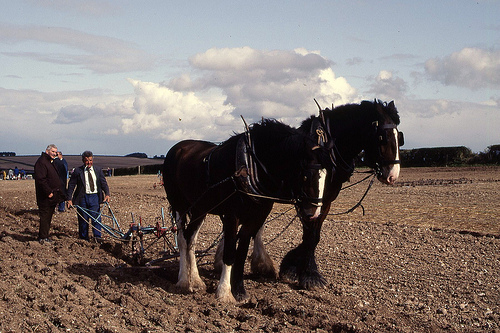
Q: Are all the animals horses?
A: Yes, all the animals are horses.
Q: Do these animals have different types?
A: No, all the animals are horses.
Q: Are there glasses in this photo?
A: No, there are no glasses.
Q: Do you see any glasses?
A: No, there are no glasses.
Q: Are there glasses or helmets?
A: No, there are no glasses or helmets.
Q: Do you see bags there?
A: No, there are no bags.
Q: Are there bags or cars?
A: No, there are no bags or cars.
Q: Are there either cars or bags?
A: No, there are no bags or cars.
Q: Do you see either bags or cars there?
A: No, there are no bags or cars.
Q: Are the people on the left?
A: Yes, the people are on the left of the image.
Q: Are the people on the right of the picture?
A: No, the people are on the left of the image.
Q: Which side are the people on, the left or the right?
A: The people are on the left of the image.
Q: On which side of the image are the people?
A: The people are on the left of the image.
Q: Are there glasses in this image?
A: No, there are no glasses.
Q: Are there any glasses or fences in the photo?
A: No, there are no glasses or fences.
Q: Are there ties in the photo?
A: Yes, there is a tie.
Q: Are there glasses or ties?
A: Yes, there is a tie.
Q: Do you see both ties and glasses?
A: No, there is a tie but no glasses.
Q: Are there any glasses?
A: No, there are no glasses.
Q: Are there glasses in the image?
A: No, there are no glasses.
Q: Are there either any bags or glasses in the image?
A: No, there are no glasses or bags.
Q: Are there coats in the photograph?
A: Yes, there is a coat.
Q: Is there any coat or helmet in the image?
A: Yes, there is a coat.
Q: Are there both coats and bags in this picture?
A: No, there is a coat but no bags.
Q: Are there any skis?
A: No, there are no skis.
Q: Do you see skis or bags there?
A: No, there are no skis or bags.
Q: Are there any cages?
A: No, there are no cages.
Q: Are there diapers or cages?
A: No, there are no cages or diapers.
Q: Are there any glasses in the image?
A: No, there are no glasses.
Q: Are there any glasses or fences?
A: No, there are no glasses or fences.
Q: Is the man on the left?
A: Yes, the man is on the left of the image.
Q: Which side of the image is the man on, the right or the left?
A: The man is on the left of the image.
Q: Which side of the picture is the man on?
A: The man is on the left of the image.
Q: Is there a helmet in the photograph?
A: No, there are no helmets.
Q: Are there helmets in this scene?
A: No, there are no helmets.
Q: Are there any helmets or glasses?
A: No, there are no helmets or glasses.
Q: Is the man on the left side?
A: Yes, the man is on the left of the image.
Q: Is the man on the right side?
A: No, the man is on the left of the image.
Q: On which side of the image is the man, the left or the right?
A: The man is on the left of the image.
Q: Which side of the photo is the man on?
A: The man is on the left of the image.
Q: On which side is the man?
A: The man is on the left of the image.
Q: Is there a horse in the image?
A: Yes, there are horses.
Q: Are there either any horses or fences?
A: Yes, there are horses.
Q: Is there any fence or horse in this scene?
A: Yes, there are horses.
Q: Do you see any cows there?
A: No, there are no cows.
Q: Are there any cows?
A: No, there are no cows.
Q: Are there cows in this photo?
A: No, there are no cows.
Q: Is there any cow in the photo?
A: No, there are no cows.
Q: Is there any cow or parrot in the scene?
A: No, there are no cows or parrots.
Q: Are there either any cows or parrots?
A: No, there are no cows or parrots.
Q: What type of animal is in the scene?
A: The animal is horses.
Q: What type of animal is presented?
A: The animal is horses.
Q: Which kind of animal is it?
A: The animals are horses.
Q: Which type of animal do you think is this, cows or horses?
A: These are horses.